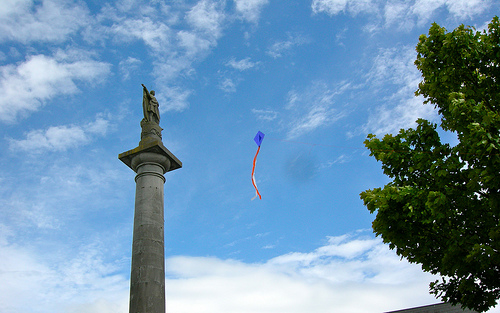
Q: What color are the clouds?
A: White.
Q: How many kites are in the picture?
A: One.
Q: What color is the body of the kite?
A: Blue.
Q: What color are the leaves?
A: Green.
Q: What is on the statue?
A: A man.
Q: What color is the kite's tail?
A: Yellow and red.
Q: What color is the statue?
A: Grey.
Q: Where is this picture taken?
A: At a park.